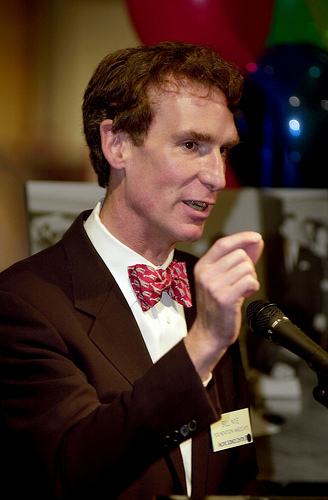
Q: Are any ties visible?
A: Yes, there is a tie.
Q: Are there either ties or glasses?
A: Yes, there is a tie.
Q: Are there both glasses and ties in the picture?
A: No, there is a tie but no glasses.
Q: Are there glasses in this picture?
A: No, there are no glasses.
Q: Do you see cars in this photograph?
A: No, there are no cars.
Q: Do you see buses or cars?
A: No, there are no cars or buses.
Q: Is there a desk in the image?
A: No, there are no desks.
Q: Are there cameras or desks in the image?
A: No, there are no desks or cameras.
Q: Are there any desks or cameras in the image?
A: No, there are no desks or cameras.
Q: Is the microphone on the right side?
A: Yes, the microphone is on the right of the image.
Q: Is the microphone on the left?
A: No, the microphone is on the right of the image.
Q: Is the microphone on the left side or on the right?
A: The microphone is on the right of the image.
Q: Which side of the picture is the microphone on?
A: The microphone is on the right of the image.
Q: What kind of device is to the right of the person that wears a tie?
A: The device is a microphone.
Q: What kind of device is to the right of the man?
A: The device is a microphone.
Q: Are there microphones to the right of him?
A: Yes, there is a microphone to the right of the man.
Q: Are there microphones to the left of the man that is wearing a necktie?
A: No, the microphone is to the right of the man.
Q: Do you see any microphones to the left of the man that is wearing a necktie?
A: No, the microphone is to the right of the man.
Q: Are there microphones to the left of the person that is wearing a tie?
A: No, the microphone is to the right of the man.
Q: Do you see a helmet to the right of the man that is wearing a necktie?
A: No, there is a microphone to the right of the man.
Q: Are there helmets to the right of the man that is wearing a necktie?
A: No, there is a microphone to the right of the man.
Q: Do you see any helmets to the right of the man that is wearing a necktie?
A: No, there is a microphone to the right of the man.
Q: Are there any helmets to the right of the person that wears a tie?
A: No, there is a microphone to the right of the man.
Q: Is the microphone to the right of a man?
A: Yes, the microphone is to the right of a man.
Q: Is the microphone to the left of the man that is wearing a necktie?
A: No, the microphone is to the right of the man.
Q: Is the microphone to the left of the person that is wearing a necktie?
A: No, the microphone is to the right of the man.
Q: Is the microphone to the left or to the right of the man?
A: The microphone is to the right of the man.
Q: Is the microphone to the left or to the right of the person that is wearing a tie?
A: The microphone is to the right of the man.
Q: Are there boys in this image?
A: No, there are no boys.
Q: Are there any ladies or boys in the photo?
A: No, there are no boys or ladies.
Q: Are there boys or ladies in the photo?
A: No, there are no boys or ladies.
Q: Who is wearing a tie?
A: The man is wearing a tie.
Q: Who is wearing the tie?
A: The man is wearing a tie.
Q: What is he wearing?
A: The man is wearing a tie.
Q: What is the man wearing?
A: The man is wearing a tie.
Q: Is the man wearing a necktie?
A: Yes, the man is wearing a necktie.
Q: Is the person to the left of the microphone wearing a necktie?
A: Yes, the man is wearing a necktie.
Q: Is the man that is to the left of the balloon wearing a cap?
A: No, the man is wearing a necktie.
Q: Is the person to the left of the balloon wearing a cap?
A: No, the man is wearing a necktie.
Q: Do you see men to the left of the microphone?
A: Yes, there is a man to the left of the microphone.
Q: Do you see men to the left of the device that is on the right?
A: Yes, there is a man to the left of the microphone.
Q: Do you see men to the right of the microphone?
A: No, the man is to the left of the microphone.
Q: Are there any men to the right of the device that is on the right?
A: No, the man is to the left of the microphone.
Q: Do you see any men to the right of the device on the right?
A: No, the man is to the left of the microphone.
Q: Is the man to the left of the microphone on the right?
A: Yes, the man is to the left of the microphone.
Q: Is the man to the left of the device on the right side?
A: Yes, the man is to the left of the microphone.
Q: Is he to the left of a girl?
A: No, the man is to the left of the microphone.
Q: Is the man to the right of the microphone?
A: No, the man is to the left of the microphone.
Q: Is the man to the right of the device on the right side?
A: No, the man is to the left of the microphone.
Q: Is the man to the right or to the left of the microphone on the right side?
A: The man is to the left of the microphone.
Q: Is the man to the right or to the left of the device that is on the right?
A: The man is to the left of the microphone.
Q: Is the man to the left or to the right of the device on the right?
A: The man is to the left of the microphone.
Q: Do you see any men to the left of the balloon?
A: Yes, there is a man to the left of the balloon.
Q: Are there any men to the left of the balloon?
A: Yes, there is a man to the left of the balloon.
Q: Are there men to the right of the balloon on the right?
A: No, the man is to the left of the balloon.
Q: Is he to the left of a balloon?
A: Yes, the man is to the left of a balloon.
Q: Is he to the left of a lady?
A: No, the man is to the left of a balloon.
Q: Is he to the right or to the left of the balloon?
A: The man is to the left of the balloon.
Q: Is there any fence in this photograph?
A: No, there are no fences.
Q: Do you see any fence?
A: No, there are no fences.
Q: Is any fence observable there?
A: No, there are no fences.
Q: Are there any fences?
A: No, there are no fences.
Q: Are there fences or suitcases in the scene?
A: No, there are no fences or suitcases.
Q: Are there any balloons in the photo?
A: Yes, there is a balloon.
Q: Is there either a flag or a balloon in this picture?
A: Yes, there is a balloon.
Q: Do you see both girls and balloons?
A: No, there is a balloon but no girls.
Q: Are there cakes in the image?
A: No, there are no cakes.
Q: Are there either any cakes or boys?
A: No, there are no cakes or boys.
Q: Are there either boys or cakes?
A: No, there are no cakes or boys.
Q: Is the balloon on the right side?
A: Yes, the balloon is on the right of the image.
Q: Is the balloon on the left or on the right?
A: The balloon is on the right of the image.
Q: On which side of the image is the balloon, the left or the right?
A: The balloon is on the right of the image.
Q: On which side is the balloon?
A: The balloon is on the right of the image.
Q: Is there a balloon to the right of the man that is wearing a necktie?
A: Yes, there is a balloon to the right of the man.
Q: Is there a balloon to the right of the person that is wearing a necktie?
A: Yes, there is a balloon to the right of the man.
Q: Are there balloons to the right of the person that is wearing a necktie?
A: Yes, there is a balloon to the right of the man.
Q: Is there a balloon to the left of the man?
A: No, the balloon is to the right of the man.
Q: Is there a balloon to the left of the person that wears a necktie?
A: No, the balloon is to the right of the man.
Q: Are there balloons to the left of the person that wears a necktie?
A: No, the balloon is to the right of the man.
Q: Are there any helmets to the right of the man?
A: No, there is a balloon to the right of the man.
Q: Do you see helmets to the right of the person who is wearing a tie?
A: No, there is a balloon to the right of the man.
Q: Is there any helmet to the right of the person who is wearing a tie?
A: No, there is a balloon to the right of the man.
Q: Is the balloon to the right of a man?
A: Yes, the balloon is to the right of a man.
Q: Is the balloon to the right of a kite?
A: No, the balloon is to the right of a man.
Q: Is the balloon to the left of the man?
A: No, the balloon is to the right of the man.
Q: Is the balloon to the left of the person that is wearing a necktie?
A: No, the balloon is to the right of the man.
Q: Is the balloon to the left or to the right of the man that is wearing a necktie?
A: The balloon is to the right of the man.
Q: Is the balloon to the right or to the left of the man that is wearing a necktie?
A: The balloon is to the right of the man.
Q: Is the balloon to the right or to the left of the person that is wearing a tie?
A: The balloon is to the right of the man.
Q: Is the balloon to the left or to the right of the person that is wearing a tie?
A: The balloon is to the right of the man.